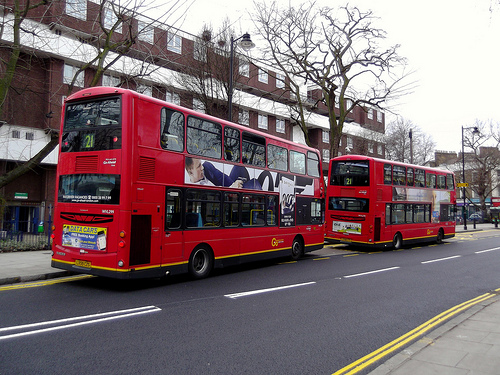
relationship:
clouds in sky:
[106, 0, 499, 162] [147, 1, 497, 152]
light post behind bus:
[458, 122, 482, 232] [329, 149, 458, 248]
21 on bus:
[344, 176, 353, 186] [329, 149, 458, 248]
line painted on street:
[225, 274, 316, 301] [0, 228, 497, 372]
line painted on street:
[339, 263, 408, 281] [0, 228, 497, 372]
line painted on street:
[421, 253, 462, 270] [0, 228, 497, 372]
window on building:
[135, 19, 156, 44] [419, 146, 500, 223]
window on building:
[231, 103, 252, 125] [419, 146, 500, 223]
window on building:
[320, 127, 331, 144] [206, 52, 422, 167]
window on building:
[271, 66, 296, 94] [212, 36, 421, 218]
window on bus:
[61, 91, 123, 133] [47, 83, 329, 283]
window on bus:
[55, 170, 122, 208] [47, 83, 329, 283]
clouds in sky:
[106, 0, 499, 162] [109, 0, 496, 162]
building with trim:
[419, 146, 500, 223] [1, 14, 386, 144]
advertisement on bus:
[185, 155, 317, 200] [47, 83, 329, 283]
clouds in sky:
[106, 0, 500, 158] [408, 29, 488, 111]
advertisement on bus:
[183, 164, 297, 199] [79, 69, 326, 268]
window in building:
[258, 66, 270, 83] [419, 146, 500, 223]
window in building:
[236, 56, 253, 78] [419, 146, 500, 223]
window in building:
[164, 31, 184, 55] [419, 146, 500, 223]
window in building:
[61, 0, 90, 20] [419, 146, 500, 223]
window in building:
[254, 111, 274, 132] [419, 146, 500, 223]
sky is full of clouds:
[343, 0, 480, 107] [448, 9, 496, 121]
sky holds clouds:
[343, 0, 480, 107] [448, 9, 496, 121]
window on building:
[162, 27, 215, 69] [419, 146, 500, 223]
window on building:
[254, 112, 271, 132] [419, 146, 500, 223]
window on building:
[190, 95, 209, 114] [419, 146, 500, 223]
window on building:
[59, 60, 87, 84] [23, 48, 106, 78]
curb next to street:
[359, 290, 493, 373] [0, 228, 497, 372]